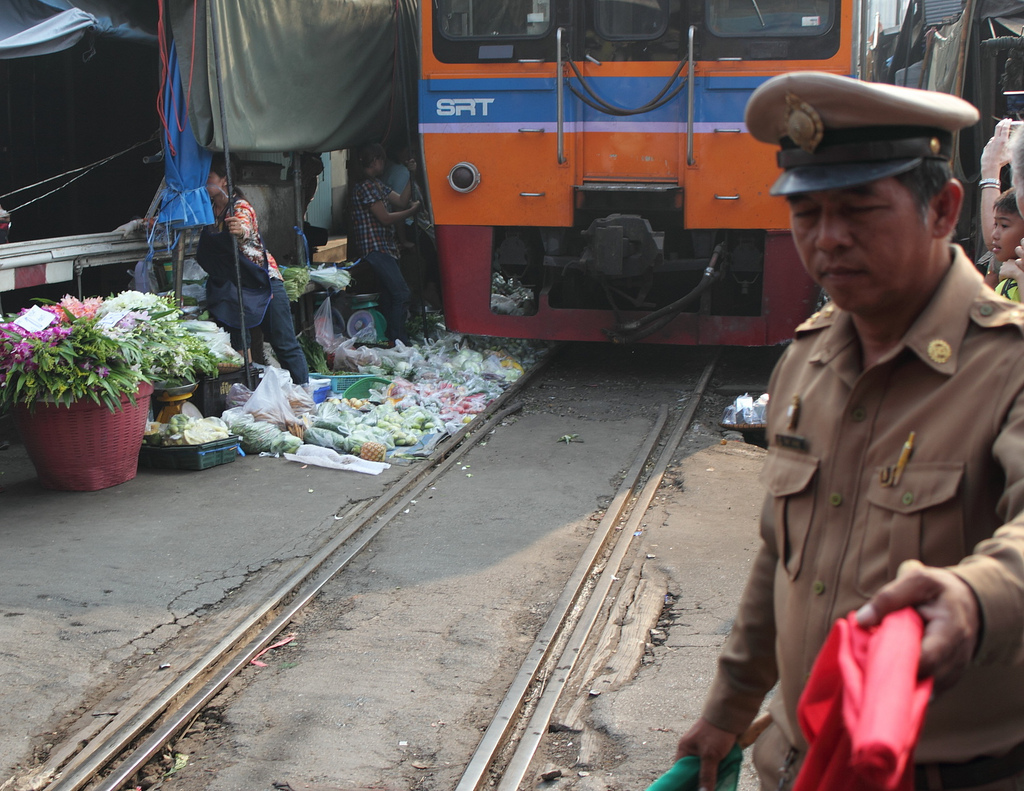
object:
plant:
[0, 290, 239, 417]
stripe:
[417, 75, 775, 122]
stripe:
[417, 122, 749, 134]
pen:
[893, 431, 917, 486]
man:
[673, 71, 1023, 791]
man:
[197, 159, 310, 385]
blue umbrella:
[158, 39, 216, 320]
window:
[419, 0, 851, 79]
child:
[974, 117, 1024, 302]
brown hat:
[744, 69, 977, 196]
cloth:
[699, 241, 1024, 791]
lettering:
[436, 99, 494, 116]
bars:
[488, 190, 765, 317]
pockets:
[759, 447, 820, 581]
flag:
[644, 744, 743, 791]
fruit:
[142, 335, 555, 475]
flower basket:
[16, 378, 151, 490]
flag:
[791, 606, 934, 791]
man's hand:
[852, 559, 976, 692]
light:
[447, 161, 482, 193]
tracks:
[36, 342, 720, 791]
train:
[417, 0, 875, 348]